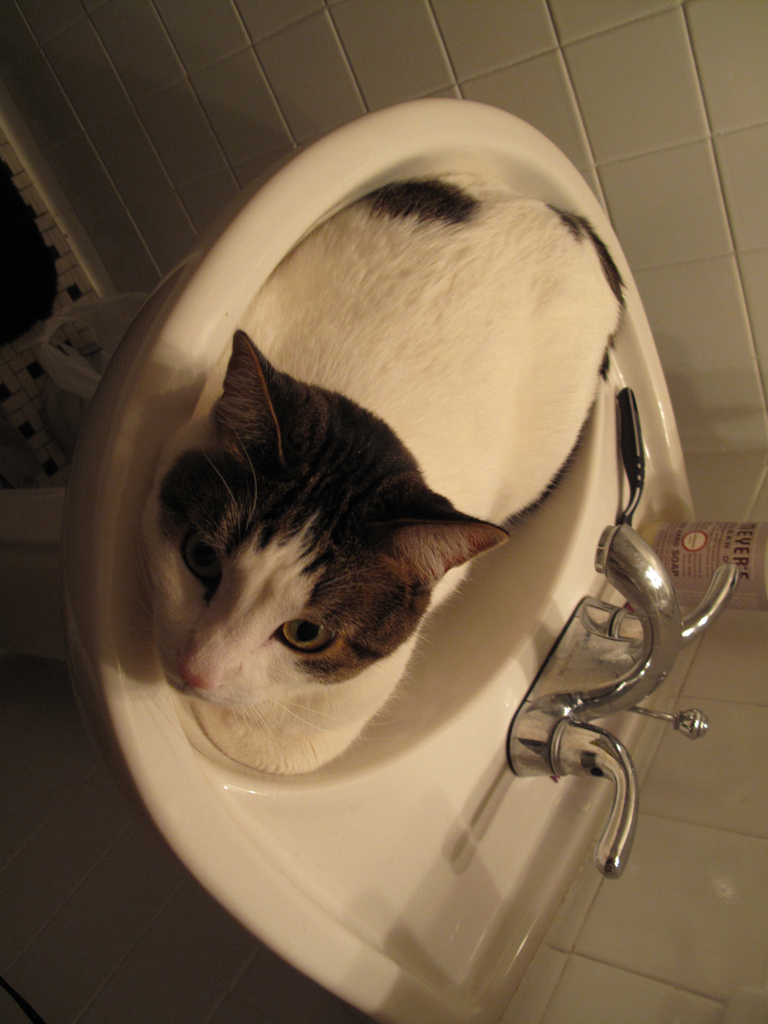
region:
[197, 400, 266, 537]
whisker on cat face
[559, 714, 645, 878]
handle attached to faucet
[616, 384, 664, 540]
razon on top of sink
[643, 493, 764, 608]
bottle on top of basin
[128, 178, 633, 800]
brown and white cat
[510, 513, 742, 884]
faucet attached to sink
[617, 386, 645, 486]
A black handle with gray line.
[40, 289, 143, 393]
plastic unde the lavatory.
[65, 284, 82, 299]
A small and black tile.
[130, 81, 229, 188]
A white and rectangular tile.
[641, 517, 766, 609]
A bottle of liquid soap.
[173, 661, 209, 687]
A small pink nose.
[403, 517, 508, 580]
Cats' ear with hair inside.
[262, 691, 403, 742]
Thin and long whiskers.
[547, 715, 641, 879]
Stainless steel switch of faucet.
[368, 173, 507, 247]
White hair with black spot.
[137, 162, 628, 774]
the multi colored cat is lying down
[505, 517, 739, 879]
the water fixture is silver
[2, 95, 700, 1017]
the pedastel sink is white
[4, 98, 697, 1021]
the cat is lying in the sink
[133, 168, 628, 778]
the cat lying down has whiskers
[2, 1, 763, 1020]
the tiles on the walls next to the white sink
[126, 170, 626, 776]
the cat has two eyes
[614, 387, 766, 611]
the bottle next to the razor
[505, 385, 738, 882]
the water fixture is next to the razor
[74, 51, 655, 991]
A cat inside a sink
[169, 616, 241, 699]
The pink nose of a cat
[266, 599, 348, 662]
A domestic cat's eye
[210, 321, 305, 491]
The ear of a cat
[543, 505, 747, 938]
A stainless sink faucet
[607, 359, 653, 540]
A razor blade for shaving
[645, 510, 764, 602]
A bottle of liquid soap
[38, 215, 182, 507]
A small garbage bin.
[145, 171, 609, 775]
white and gray cat sitting inside a sink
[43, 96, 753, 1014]
white sink with silver faucet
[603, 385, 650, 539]
black razor lying on the sink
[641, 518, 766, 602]
plastic soap bottle sitting on sink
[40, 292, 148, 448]
plastic bag sitting near sink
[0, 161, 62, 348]
black item laying near plastic bag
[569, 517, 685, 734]
silver metal faucet on sink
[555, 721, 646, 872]
silver metal handle on sink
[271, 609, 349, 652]
green and yellow cat eye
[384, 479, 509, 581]
pink and brown cat ear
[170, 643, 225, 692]
pink and white cat nose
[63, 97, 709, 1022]
large white sink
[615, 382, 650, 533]
black and silver razor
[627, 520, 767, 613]
tall plastic clear bottle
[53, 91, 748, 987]
Cat on the sink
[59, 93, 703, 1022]
Cat on the white sink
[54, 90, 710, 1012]
black and white cat on the sink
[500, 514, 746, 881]
Faucet has hot and cold knob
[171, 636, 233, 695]
Pinkish nose of the cat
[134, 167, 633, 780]
Cat is black and white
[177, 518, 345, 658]
Eyes of the cat are wide open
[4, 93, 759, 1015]
White pedestal sink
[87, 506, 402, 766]
Long white whiskers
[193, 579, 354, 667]
The eyes of the cat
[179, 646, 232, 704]
The nose of the cat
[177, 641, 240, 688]
A nose on the cat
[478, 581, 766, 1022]
The tiled wall